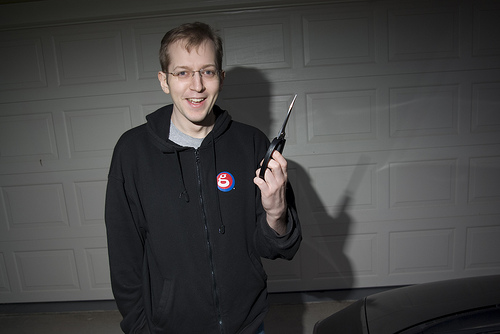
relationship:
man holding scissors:
[103, 23, 302, 333] [257, 93, 299, 180]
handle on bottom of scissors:
[260, 134, 285, 181] [257, 93, 299, 180]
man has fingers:
[103, 23, 302, 333] [253, 150, 288, 197]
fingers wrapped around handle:
[253, 150, 288, 197] [260, 134, 285, 181]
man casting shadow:
[103, 23, 302, 333] [217, 65, 353, 333]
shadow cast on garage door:
[217, 65, 353, 333] [0, 1, 499, 304]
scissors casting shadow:
[257, 93, 299, 180] [336, 154, 369, 215]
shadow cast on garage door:
[336, 154, 369, 215] [0, 1, 499, 304]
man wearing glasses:
[103, 23, 302, 333] [162, 66, 220, 79]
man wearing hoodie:
[103, 23, 302, 333] [105, 100, 303, 333]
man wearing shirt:
[103, 23, 302, 333] [168, 118, 203, 150]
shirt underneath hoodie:
[168, 118, 203, 150] [105, 100, 303, 333]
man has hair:
[103, 23, 302, 333] [157, 22, 223, 82]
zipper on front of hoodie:
[194, 146, 224, 334] [105, 100, 303, 333]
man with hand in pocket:
[103, 23, 302, 333] [151, 274, 175, 328]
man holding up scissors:
[103, 23, 302, 333] [257, 93, 299, 180]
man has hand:
[103, 23, 302, 333] [253, 149, 288, 222]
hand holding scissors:
[253, 149, 288, 222] [257, 93, 299, 180]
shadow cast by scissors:
[336, 154, 369, 215] [257, 93, 299, 180]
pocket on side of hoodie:
[151, 274, 175, 328] [105, 100, 303, 333]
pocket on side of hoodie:
[248, 250, 267, 289] [105, 100, 303, 333]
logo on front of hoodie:
[214, 171, 237, 194] [105, 100, 303, 333]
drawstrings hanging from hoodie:
[171, 152, 192, 200] [105, 100, 303, 333]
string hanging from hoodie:
[208, 132, 225, 235] [105, 100, 303, 333]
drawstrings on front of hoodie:
[171, 134, 225, 236] [105, 100, 303, 333]